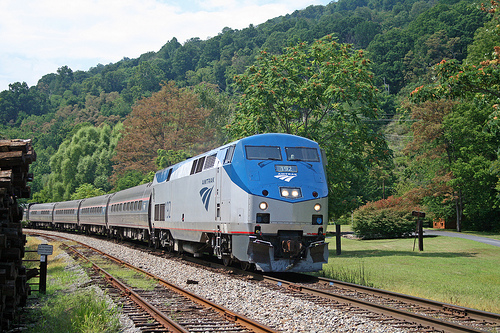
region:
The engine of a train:
[256, 235, 334, 273]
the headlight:
[258, 201, 269, 212]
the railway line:
[101, 257, 183, 308]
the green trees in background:
[208, 48, 409, 124]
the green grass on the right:
[368, 240, 485, 292]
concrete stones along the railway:
[236, 283, 263, 311]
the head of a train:
[241, 142, 335, 229]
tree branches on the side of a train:
[292, 98, 353, 136]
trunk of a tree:
[413, 218, 435, 252]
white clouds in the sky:
[33, 14, 117, 58]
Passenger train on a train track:
[21, 132, 330, 275]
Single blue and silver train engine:
[150, 132, 328, 273]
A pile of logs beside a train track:
[0, 138, 38, 331]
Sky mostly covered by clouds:
[0, 1, 340, 93]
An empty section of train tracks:
[21, 230, 279, 331]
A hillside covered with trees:
[0, 1, 498, 233]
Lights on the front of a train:
[259, 189, 321, 211]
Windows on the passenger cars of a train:
[29, 199, 144, 216]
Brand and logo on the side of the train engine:
[198, 176, 215, 213]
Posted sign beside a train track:
[36, 243, 54, 295]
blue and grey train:
[42, 165, 340, 276]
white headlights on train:
[258, 171, 323, 225]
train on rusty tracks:
[311, 268, 455, 325]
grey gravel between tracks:
[192, 267, 307, 331]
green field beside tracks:
[361, 244, 495, 316]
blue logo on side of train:
[190, 171, 227, 203]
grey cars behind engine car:
[18, 185, 182, 230]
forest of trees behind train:
[71, 71, 498, 223]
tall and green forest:
[47, 67, 472, 205]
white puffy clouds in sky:
[25, 0, 197, 75]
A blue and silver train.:
[18, 129, 330, 286]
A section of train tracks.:
[19, 223, 499, 332]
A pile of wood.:
[0, 139, 37, 331]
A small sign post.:
[33, 240, 54, 295]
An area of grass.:
[13, 233, 124, 332]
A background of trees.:
[0, 1, 498, 237]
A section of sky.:
[0, 0, 340, 97]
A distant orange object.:
[433, 211, 447, 232]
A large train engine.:
[148, 131, 328, 283]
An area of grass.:
[321, 220, 498, 310]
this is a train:
[37, 125, 347, 284]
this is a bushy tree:
[219, 34, 411, 226]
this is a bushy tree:
[396, 83, 458, 238]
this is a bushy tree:
[344, 178, 424, 260]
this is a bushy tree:
[422, 47, 499, 227]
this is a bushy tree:
[112, 85, 215, 181]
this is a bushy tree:
[26, 120, 140, 204]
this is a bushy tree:
[167, 71, 248, 195]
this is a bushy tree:
[345, 26, 442, 205]